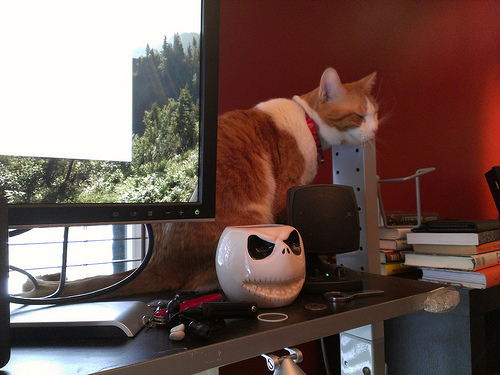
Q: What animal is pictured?
A: A cat.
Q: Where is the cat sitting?
A: On the desk.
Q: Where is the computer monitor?
A: On the desk.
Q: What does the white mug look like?
A: A skull.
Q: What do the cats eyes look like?
A: They are closed.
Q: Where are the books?
A: To the right of the desk.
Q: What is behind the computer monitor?
A: A window.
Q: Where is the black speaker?
A: In front of the cat.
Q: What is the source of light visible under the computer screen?
A: Window.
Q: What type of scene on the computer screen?
A: Nature.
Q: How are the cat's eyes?
A: Closed.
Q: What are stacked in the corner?
A: Books.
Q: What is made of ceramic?
A: The pumpkin.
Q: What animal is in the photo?
A: A kitty.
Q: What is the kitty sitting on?
A: A desk.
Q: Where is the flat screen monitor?
A: On the desk.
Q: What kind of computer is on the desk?
A: A black one.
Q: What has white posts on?
A: The outlet by the kitty.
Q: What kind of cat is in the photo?
A: A tabby.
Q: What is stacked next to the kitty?
A: Books.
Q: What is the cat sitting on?
A: DEsk.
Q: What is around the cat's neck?
A: Collar.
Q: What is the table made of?
A: Metal.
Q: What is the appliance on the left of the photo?
A: TV.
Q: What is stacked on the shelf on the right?
A: Books.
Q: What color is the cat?
A: Orange and white.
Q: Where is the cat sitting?
A: On a computer desk.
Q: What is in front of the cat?
A: A speaker.